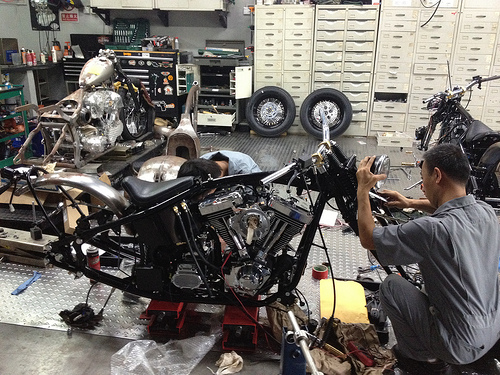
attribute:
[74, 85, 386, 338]
motorcycle — partially disassembled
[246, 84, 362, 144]
wheels — black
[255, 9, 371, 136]
drawers — white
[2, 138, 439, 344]
covering — metal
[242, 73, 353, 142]
tires — black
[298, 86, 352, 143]
tire — black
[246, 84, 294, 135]
tire — black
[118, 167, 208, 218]
seat — black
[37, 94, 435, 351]
motorcycle — unarmed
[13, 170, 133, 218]
fender — rear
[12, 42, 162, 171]
motorcycle — white, unarmed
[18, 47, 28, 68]
can — red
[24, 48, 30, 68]
can — red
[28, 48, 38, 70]
can — red